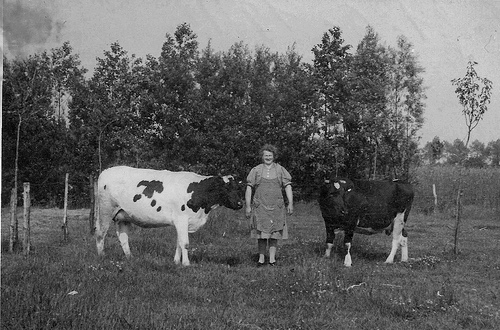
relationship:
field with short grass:
[2, 206, 469, 326] [7, 231, 496, 329]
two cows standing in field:
[68, 144, 446, 300] [2, 206, 469, 326]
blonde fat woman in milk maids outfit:
[239, 133, 304, 271] [246, 163, 291, 240]